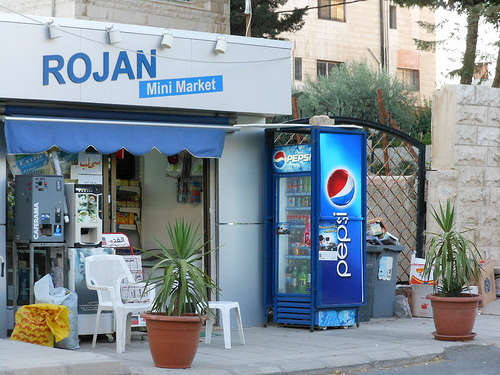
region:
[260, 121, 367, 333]
The soda is pepsi.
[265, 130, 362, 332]
The cooler is blue.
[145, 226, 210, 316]
The plant is green.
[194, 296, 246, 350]
The stool is white.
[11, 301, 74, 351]
The bag is yellow.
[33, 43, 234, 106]
The name of the market is Rojan.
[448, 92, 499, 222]
This wall is stone.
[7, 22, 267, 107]
This sign is blue and white.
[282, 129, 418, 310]
This gate is black.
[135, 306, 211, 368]
This pot is orange.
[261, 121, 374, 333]
A machine vending Pepsi.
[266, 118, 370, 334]
A vending machine.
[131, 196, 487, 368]
Two plants in pots.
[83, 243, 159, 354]
A white plastic chair in front of the store.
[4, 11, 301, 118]
A white roof with blue writing on it.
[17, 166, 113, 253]
Liquid dispensers in front of the store.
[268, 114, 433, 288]
a fence behind the vending machine.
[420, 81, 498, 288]
A brick wall.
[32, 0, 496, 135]
A building in the background.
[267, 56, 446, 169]
Bushes behind the fence.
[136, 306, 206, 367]
the pot is orange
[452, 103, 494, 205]
the wall is gray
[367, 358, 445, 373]
the brown leaves are on the ground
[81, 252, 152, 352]
the chair is white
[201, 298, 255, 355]
the stool is behind the plant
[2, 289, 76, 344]
the bag is yellow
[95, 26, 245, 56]
the lights are off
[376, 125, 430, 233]
the gate is black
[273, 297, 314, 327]
the cooler has vents on the bottom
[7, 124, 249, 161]
the awning is blue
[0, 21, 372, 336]
vending machine outside the store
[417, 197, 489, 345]
plant in a pot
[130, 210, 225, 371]
a plant in a pot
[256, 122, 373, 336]
the vending machine is blue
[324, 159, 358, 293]
the vending machine of Pepsi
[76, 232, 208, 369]
white chair in front a pot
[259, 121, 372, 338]
vending machine color blue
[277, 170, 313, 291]
cans and bottles in vending machine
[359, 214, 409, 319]
the trash can is full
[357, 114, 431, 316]
a metal door behind a trash can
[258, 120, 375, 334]
pepsi soda machine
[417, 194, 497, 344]
plant in clay pot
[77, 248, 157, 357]
white plastic chair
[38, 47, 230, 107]
blue sign on front of building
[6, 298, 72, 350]
yellow bag on front of building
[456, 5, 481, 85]
brown tree trunk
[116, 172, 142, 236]
shelves on wall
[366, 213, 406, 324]
trash cans behind soda machine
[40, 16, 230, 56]
lights at top of building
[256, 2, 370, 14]
black power line in sky